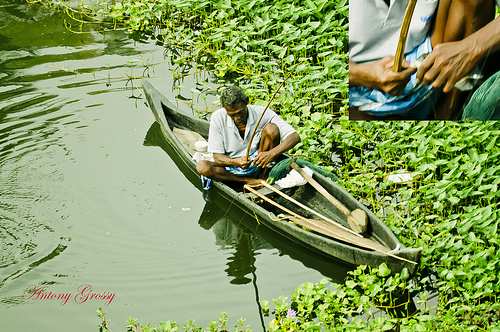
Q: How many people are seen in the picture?
A: One.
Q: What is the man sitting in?
A: A canoe.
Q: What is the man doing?
A: Fishing.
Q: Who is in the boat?
A: A man.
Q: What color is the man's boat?
A: Green.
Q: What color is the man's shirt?
A: Blue.